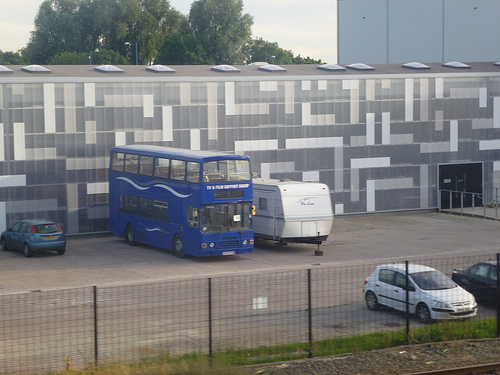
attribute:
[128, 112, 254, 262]
bus — parked, blue, double decker, tall, passenger, double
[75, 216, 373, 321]
lot — parking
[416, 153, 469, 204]
door — large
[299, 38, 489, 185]
building — here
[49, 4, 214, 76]
trees — behind, growing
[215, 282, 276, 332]
fence — black, tall, metal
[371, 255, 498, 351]
vehicle — parked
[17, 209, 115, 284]
car — blue, parked, gren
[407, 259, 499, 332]
car — white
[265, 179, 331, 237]
camper — behind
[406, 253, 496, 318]
cars — behind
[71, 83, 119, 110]
square — white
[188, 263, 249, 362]
post — black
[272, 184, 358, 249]
trailer — white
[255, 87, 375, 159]
stone — grey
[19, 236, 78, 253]
plate — yellow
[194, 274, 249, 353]
pole — bar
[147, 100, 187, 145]
strip — white